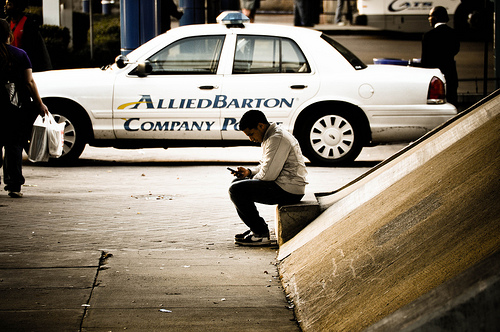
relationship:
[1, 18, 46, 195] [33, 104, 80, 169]
man carrying bag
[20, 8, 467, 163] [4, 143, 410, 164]
car on road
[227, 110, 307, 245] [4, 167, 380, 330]
man sitting on sidewalk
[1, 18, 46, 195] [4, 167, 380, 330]
man sitting on sidewalk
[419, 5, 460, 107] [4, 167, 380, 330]
man sitting on sidewalk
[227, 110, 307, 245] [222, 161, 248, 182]
man looking at phone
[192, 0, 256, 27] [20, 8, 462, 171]
lights on top of car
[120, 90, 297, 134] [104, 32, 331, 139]
logo on doors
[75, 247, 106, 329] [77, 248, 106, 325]
part on line